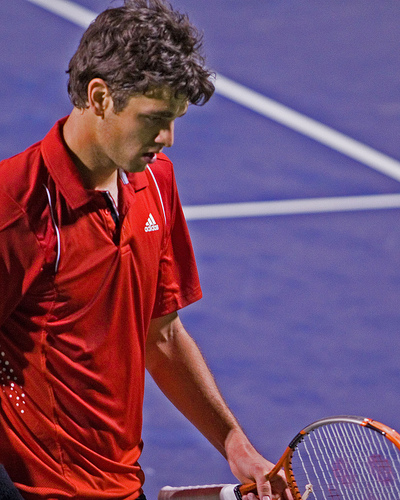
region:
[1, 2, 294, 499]
a male tennis player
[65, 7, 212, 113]
the curly brown hair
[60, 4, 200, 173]
the head of the tennis player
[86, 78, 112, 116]
the ear on the head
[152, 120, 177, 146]
the nose of the face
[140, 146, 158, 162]
the mouth of the face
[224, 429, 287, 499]
the hand of the man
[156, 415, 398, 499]
the orange black and silver tennis racket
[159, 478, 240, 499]
the white taped handle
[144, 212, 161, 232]
the adidas logo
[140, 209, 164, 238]
company logo on front of shirt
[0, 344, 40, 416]
design on side of shirt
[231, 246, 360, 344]
orange turf on tennis court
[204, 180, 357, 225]
white line on tennis court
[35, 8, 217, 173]
man with dark hair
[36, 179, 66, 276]
white stripe on tennis shirt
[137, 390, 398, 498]
black and orange tennis racquet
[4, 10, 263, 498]
man in red tennis shirt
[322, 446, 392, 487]
design on tennis racquet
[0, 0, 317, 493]
man walking on tennis court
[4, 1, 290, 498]
tennis player wears red shirt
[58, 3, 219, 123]
dark brown curly hair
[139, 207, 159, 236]
white logo on red shirt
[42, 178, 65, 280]
white stripe on red shirt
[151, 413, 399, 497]
black red and white tennis racket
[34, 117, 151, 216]
collar of a red shirt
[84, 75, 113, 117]
man's right ear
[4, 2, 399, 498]
blue tennis court surface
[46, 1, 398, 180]
white marking on tennis court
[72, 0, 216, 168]
man with brown curly hair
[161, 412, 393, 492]
man holding a tennis racket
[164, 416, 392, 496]
an orange tennis racket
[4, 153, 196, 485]
man wearing a red Adidas shirt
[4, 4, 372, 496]
a tennis player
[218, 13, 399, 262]
a blue tennis court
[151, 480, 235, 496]
white and orange handle of a tennis racket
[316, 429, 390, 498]
white strings with red spots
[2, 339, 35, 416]
white dots on a red shirt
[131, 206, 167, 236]
a white logo on ared shirt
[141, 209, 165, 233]
Logo on a tennis shirt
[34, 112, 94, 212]
Collar on a tennis shirt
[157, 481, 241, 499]
Handle of a tennis racket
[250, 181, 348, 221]
Lines of a tennis court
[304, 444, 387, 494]
Mesh of strings in a tennis racket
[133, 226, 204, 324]
Short sleeves of a tennis shirt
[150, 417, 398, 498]
Tennis racket held by tennis player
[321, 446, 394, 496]
Logo in the strings of a tennis racket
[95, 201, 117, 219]
Button on a tennis shirt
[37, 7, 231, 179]
Tennis player concentrating on game